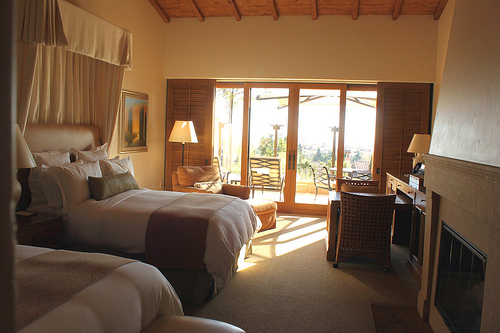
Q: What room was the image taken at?
A: It was taken at the bedroom.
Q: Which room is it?
A: It is a bedroom.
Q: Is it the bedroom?
A: Yes, it is the bedroom.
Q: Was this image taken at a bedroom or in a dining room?
A: It was taken at a bedroom.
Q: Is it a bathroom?
A: No, it is a bedroom.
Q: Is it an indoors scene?
A: Yes, it is indoors.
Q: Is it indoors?
A: Yes, it is indoors.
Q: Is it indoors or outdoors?
A: It is indoors.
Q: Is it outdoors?
A: No, it is indoors.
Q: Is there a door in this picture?
A: Yes, there is a door.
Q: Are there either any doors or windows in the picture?
A: Yes, there is a door.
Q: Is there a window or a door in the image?
A: Yes, there is a door.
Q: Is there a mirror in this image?
A: No, there are no mirrors.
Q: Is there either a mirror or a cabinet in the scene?
A: No, there are no mirrors or cabinets.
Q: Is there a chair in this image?
A: Yes, there is a chair.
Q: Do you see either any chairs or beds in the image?
A: Yes, there is a chair.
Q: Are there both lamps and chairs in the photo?
A: Yes, there are both a chair and a lamp.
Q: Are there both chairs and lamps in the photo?
A: Yes, there are both a chair and a lamp.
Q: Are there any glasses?
A: No, there are no glasses.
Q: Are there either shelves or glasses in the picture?
A: No, there are no glasses or shelves.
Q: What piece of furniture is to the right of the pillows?
A: The piece of furniture is a chair.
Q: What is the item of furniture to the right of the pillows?
A: The piece of furniture is a chair.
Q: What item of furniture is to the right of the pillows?
A: The piece of furniture is a chair.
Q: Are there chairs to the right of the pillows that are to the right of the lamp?
A: Yes, there is a chair to the right of the pillows.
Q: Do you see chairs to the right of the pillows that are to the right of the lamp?
A: Yes, there is a chair to the right of the pillows.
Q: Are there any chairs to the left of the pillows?
A: No, the chair is to the right of the pillows.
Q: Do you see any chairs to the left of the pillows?
A: No, the chair is to the right of the pillows.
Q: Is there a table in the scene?
A: Yes, there is a table.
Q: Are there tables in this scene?
A: Yes, there is a table.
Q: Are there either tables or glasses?
A: Yes, there is a table.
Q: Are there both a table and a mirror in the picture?
A: No, there is a table but no mirrors.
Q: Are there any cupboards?
A: No, there are no cupboards.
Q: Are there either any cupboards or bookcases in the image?
A: No, there are no cupboards or bookcases.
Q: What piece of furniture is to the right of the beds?
A: The piece of furniture is a table.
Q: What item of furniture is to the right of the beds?
A: The piece of furniture is a table.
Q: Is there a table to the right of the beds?
A: Yes, there is a table to the right of the beds.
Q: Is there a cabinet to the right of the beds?
A: No, there is a table to the right of the beds.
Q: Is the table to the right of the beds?
A: Yes, the table is to the right of the beds.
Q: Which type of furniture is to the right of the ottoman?
A: The piece of furniture is a table.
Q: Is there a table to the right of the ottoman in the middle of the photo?
A: Yes, there is a table to the right of the ottoman.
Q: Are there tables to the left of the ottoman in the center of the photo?
A: No, the table is to the right of the ottoman.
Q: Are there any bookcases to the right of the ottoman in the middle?
A: No, there is a table to the right of the ottoman.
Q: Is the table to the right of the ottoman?
A: Yes, the table is to the right of the ottoman.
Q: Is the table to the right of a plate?
A: No, the table is to the right of the ottoman.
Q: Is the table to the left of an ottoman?
A: No, the table is to the right of an ottoman.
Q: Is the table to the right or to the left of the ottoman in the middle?
A: The table is to the right of the ottoman.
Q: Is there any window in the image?
A: Yes, there are windows.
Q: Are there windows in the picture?
A: Yes, there are windows.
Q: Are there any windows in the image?
A: Yes, there are windows.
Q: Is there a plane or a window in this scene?
A: Yes, there are windows.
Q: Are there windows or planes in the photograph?
A: Yes, there are windows.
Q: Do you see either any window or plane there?
A: Yes, there are windows.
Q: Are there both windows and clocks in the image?
A: No, there are windows but no clocks.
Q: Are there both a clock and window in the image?
A: No, there are windows but no clocks.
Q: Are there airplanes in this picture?
A: No, there are no airplanes.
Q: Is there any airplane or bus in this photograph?
A: No, there are no airplanes or buses.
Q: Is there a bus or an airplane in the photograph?
A: No, there are no airplanes or buses.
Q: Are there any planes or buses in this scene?
A: No, there are no planes or buses.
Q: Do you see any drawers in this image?
A: No, there are no drawers.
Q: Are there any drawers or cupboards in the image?
A: No, there are no drawers or cupboards.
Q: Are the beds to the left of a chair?
A: Yes, the beds are to the left of a chair.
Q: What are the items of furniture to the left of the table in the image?
A: The pieces of furniture are beds.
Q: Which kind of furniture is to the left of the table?
A: The pieces of furniture are beds.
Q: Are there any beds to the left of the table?
A: Yes, there are beds to the left of the table.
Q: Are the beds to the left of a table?
A: Yes, the beds are to the left of a table.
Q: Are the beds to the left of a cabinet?
A: No, the beds are to the left of a table.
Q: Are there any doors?
A: Yes, there is a door.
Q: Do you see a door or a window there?
A: Yes, there is a door.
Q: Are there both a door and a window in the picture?
A: Yes, there are both a door and a window.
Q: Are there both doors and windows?
A: Yes, there are both a door and windows.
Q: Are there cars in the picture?
A: No, there are no cars.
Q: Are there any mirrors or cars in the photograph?
A: No, there are no cars or mirrors.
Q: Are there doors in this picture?
A: Yes, there is a door.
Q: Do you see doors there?
A: Yes, there is a door.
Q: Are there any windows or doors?
A: Yes, there is a door.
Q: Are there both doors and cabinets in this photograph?
A: No, there is a door but no cabinets.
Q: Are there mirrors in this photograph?
A: No, there are no mirrors.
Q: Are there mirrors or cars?
A: No, there are no mirrors or cars.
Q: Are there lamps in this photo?
A: Yes, there is a lamp.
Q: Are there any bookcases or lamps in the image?
A: Yes, there is a lamp.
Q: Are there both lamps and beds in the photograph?
A: Yes, there are both a lamp and a bed.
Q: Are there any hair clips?
A: No, there are no hair clips.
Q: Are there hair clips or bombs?
A: No, there are no hair clips or bombs.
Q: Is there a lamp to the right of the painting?
A: Yes, there is a lamp to the right of the painting.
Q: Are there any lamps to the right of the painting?
A: Yes, there is a lamp to the right of the painting.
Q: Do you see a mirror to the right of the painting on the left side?
A: No, there is a lamp to the right of the painting.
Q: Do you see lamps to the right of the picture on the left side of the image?
A: Yes, there is a lamp to the right of the picture.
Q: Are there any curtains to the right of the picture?
A: No, there is a lamp to the right of the picture.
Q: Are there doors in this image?
A: Yes, there is a door.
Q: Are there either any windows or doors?
A: Yes, there is a door.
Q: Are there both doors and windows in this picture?
A: Yes, there are both a door and a window.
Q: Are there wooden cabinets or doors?
A: Yes, there is a wood door.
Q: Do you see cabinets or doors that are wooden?
A: Yes, the door is wooden.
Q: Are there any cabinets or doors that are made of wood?
A: Yes, the door is made of wood.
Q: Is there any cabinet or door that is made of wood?
A: Yes, the door is made of wood.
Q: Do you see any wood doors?
A: Yes, there is a wood door.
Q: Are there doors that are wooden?
A: Yes, there is a door that is wooden.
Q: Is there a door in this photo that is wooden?
A: Yes, there is a door that is wooden.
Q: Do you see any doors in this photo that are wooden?
A: Yes, there is a door that is wooden.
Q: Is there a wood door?
A: Yes, there is a door that is made of wood.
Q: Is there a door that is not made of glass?
A: Yes, there is a door that is made of wood.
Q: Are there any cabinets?
A: No, there are no cabinets.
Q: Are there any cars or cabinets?
A: No, there are no cabinets or cars.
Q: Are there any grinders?
A: No, there are no grinders.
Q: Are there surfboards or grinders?
A: No, there are no grinders or surfboards.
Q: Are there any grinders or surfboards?
A: No, there are no grinders or surfboards.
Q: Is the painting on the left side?
A: Yes, the painting is on the left of the image.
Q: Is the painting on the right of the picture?
A: No, the painting is on the left of the image.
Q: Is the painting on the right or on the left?
A: The painting is on the left of the image.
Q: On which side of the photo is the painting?
A: The painting is on the left of the image.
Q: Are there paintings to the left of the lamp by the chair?
A: Yes, there is a painting to the left of the lamp.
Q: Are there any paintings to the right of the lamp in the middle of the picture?
A: No, the painting is to the left of the lamp.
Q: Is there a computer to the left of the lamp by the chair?
A: No, there is a painting to the left of the lamp.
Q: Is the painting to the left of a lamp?
A: Yes, the painting is to the left of a lamp.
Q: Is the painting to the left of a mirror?
A: No, the painting is to the left of a lamp.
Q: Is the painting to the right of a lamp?
A: No, the painting is to the left of a lamp.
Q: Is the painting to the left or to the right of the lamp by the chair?
A: The painting is to the left of the lamp.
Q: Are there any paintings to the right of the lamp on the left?
A: Yes, there is a painting to the right of the lamp.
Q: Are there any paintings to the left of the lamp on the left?
A: No, the painting is to the right of the lamp.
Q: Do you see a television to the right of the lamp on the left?
A: No, there is a painting to the right of the lamp.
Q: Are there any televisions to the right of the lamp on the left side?
A: No, there is a painting to the right of the lamp.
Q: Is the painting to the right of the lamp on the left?
A: Yes, the painting is to the right of the lamp.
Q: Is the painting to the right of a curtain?
A: No, the painting is to the right of the lamp.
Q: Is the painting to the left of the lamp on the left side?
A: No, the painting is to the right of the lamp.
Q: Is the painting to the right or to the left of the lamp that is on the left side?
A: The painting is to the right of the lamp.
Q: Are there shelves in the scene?
A: No, there are no shelves.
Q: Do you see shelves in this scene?
A: No, there are no shelves.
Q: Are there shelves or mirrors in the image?
A: No, there are no shelves or mirrors.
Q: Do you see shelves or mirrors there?
A: No, there are no shelves or mirrors.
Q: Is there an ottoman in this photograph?
A: Yes, there is an ottoman.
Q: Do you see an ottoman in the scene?
A: Yes, there is an ottoman.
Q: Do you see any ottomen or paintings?
A: Yes, there is an ottoman.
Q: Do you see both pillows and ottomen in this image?
A: Yes, there are both an ottoman and a pillow.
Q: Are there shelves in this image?
A: No, there are no shelves.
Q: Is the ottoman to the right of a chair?
A: No, the ottoman is to the left of a chair.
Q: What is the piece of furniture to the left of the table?
A: The piece of furniture is an ottoman.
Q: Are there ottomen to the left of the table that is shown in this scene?
A: Yes, there is an ottoman to the left of the table.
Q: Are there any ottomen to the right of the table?
A: No, the ottoman is to the left of the table.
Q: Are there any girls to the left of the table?
A: No, there is an ottoman to the left of the table.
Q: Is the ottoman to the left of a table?
A: Yes, the ottoman is to the left of a table.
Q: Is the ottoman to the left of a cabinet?
A: No, the ottoman is to the left of a table.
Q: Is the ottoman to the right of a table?
A: No, the ottoman is to the left of a table.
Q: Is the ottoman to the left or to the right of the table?
A: The ottoman is to the left of the table.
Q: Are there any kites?
A: No, there are no kites.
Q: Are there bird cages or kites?
A: No, there are no kites or bird cages.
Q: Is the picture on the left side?
A: Yes, the picture is on the left of the image.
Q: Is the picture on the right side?
A: No, the picture is on the left of the image.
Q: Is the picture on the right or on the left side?
A: The picture is on the left of the image.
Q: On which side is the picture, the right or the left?
A: The picture is on the left of the image.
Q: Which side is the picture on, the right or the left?
A: The picture is on the left of the image.